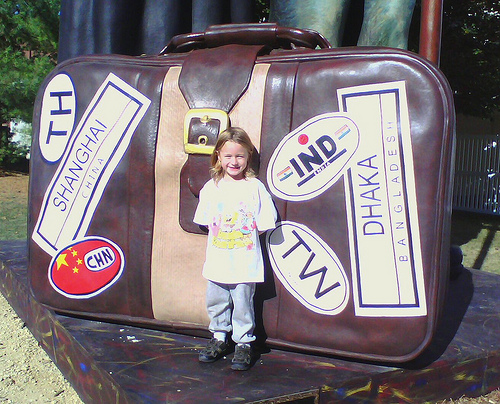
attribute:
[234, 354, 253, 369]
shoe — girl's, left shoe, girls, black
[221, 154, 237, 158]
eye — girl's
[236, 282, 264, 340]
leg — girls, girl's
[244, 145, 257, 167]
ear — girl's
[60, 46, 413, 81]
suitcase — brown, buckle, base, novelty, daytime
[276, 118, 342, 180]
sticker — red, shanghai, luggage, india, yellow, blue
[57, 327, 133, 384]
platform — red, brown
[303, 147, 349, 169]
lettering — black, blue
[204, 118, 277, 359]
girl — young, standing, blonde, posing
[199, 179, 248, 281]
shirt — white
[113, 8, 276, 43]
handle — brown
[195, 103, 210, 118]
buckle — gold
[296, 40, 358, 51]
strap — brown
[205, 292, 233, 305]
pants — gray, sweats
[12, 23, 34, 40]
leaves — green